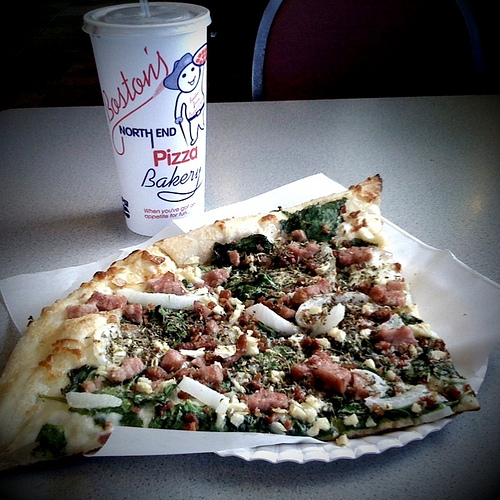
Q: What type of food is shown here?
A: Pizza.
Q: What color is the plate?
A: White.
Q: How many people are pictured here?
A: Zero.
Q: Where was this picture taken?
A: A restaurant.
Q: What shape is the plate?
A: Round.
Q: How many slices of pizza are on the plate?
A: 2.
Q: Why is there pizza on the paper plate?
A: To eat.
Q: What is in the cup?
A: Soda pop.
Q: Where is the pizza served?
A: Boston's North End Pizza Bakery.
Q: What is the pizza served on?
A: White paper plate.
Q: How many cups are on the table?
A: 1.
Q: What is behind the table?
A: A red chair.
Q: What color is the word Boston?
A: Red.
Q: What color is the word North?
A: Black.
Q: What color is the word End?
A: Black.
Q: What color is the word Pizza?
A: RED.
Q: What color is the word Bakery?
A: Black.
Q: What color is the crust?
A: Brown.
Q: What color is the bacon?
A: Red.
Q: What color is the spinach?
A: Green.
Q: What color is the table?
A: White.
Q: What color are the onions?
A: White.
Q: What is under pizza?
A: White paper.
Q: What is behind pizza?
A: Soft drink with straw.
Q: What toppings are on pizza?
A: Zesty herbs.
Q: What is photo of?
A: Pizza and beverage.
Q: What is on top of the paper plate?
A: Paper towel.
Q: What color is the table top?
A: Gray.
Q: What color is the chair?
A: Red.